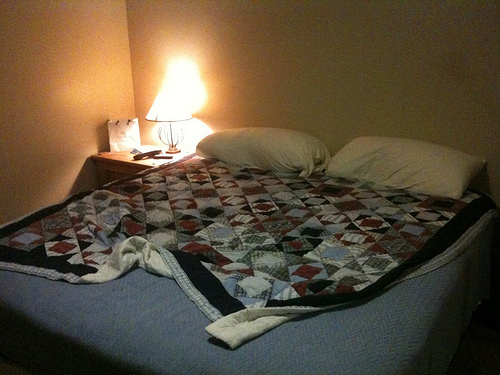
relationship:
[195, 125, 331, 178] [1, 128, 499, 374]
pillow on bed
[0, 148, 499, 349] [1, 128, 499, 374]
bedspread on bed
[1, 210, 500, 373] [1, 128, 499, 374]
blanket on bed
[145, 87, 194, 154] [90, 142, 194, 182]
lamp on table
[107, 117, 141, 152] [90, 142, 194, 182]
bag on table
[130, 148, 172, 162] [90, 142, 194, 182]
remotes on table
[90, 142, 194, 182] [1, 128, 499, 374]
table next to bed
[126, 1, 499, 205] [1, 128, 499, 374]
wall behind bed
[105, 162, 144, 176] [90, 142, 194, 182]
drawer on table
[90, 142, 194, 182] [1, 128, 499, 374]
table by bed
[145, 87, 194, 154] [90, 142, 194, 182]
lamp on top of table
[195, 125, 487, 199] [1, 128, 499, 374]
pillows on bed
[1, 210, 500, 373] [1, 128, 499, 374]
blanket on top of bed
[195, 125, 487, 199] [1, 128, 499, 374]
pillows on top of bed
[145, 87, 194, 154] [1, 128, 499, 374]
lamp next to bed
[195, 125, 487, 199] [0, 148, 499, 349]
pillows on top of bedspread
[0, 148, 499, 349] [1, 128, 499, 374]
bedspread on top of bed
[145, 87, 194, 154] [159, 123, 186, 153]
lamp has base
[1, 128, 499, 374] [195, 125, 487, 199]
bed has pillows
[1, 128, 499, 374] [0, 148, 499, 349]
bed has bedspread